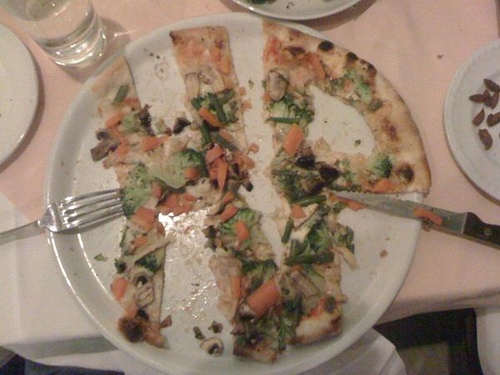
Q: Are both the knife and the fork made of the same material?
A: Yes, both the knife and the fork are made of metal.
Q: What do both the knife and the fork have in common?
A: The material, both the knife and the fork are metallic.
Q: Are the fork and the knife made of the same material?
A: Yes, both the fork and the knife are made of metal.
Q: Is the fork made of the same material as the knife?
A: Yes, both the fork and the knife are made of metal.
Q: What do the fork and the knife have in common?
A: The material, both the fork and the knife are metallic.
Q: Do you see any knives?
A: Yes, there is a knife.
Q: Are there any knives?
A: Yes, there is a knife.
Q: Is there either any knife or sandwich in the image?
A: Yes, there is a knife.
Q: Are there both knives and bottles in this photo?
A: No, there is a knife but no bottles.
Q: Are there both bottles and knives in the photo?
A: No, there is a knife but no bottles.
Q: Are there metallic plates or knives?
A: Yes, there is a metal knife.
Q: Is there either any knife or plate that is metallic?
A: Yes, the knife is metallic.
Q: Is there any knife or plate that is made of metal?
A: Yes, the knife is made of metal.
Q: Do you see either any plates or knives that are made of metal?
A: Yes, the knife is made of metal.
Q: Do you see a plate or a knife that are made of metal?
A: Yes, the knife is made of metal.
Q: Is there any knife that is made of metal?
A: Yes, there is a knife that is made of metal.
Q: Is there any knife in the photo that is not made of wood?
A: Yes, there is a knife that is made of metal.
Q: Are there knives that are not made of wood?
A: Yes, there is a knife that is made of metal.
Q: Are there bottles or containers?
A: No, there are no containers or bottles.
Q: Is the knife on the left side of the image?
A: No, the knife is on the right of the image.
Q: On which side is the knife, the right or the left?
A: The knife is on the right of the image.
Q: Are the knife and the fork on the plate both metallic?
A: Yes, both the knife and the fork are metallic.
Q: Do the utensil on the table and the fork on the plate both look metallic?
A: Yes, both the knife and the fork are metallic.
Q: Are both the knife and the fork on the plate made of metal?
A: Yes, both the knife and the fork are made of metal.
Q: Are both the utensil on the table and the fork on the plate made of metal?
A: Yes, both the knife and the fork are made of metal.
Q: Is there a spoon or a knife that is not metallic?
A: No, there is a knife but it is metallic.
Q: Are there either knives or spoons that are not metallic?
A: No, there is a knife but it is metallic.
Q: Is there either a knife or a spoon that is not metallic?
A: No, there is a knife but it is metallic.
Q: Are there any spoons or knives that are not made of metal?
A: No, there is a knife but it is made of metal.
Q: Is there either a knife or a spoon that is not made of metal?
A: No, there is a knife but it is made of metal.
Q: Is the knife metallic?
A: Yes, the knife is metallic.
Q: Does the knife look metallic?
A: Yes, the knife is metallic.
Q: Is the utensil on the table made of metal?
A: Yes, the knife is made of metal.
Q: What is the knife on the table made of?
A: The knife is made of metal.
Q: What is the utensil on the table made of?
A: The knife is made of metal.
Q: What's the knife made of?
A: The knife is made of metal.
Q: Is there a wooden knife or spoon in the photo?
A: No, there is a knife but it is metallic.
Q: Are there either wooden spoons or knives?
A: No, there is a knife but it is metallic.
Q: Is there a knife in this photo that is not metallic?
A: No, there is a knife but it is metallic.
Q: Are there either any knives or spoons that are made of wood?
A: No, there is a knife but it is made of metal.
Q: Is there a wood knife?
A: No, there is a knife but it is made of metal.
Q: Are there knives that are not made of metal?
A: No, there is a knife but it is made of metal.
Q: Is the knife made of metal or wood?
A: The knife is made of metal.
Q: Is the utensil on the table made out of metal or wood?
A: The knife is made of metal.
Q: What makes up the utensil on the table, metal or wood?
A: The knife is made of metal.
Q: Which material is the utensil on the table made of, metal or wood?
A: The knife is made of metal.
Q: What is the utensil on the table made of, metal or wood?
A: The knife is made of metal.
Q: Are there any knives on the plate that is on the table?
A: Yes, there is a knife on the plate.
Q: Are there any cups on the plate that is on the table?
A: No, there is a knife on the plate.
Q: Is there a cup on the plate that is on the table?
A: No, there is a knife on the plate.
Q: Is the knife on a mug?
A: No, the knife is on the plate.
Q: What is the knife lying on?
A: The knife is lying on the plate.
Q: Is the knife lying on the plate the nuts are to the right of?
A: Yes, the knife is lying on the plate.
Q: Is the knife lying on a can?
A: No, the knife is lying on the plate.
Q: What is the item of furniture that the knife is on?
A: The piece of furniture is a table.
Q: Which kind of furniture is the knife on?
A: The knife is on the table.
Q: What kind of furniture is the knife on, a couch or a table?
A: The knife is on a table.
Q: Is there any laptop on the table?
A: No, there is a knife on the table.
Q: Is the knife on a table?
A: Yes, the knife is on a table.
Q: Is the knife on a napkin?
A: No, the knife is on a table.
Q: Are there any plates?
A: Yes, there is a plate.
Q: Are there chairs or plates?
A: Yes, there is a plate.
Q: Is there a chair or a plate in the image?
A: Yes, there is a plate.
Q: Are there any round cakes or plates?
A: Yes, there is a round plate.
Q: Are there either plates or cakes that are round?
A: Yes, the plate is round.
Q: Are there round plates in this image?
A: Yes, there is a round plate.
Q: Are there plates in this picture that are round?
A: Yes, there is a plate that is round.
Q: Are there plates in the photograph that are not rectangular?
A: Yes, there is a round plate.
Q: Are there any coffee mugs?
A: No, there are no coffee mugs.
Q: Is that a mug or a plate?
A: That is a plate.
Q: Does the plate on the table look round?
A: Yes, the plate is round.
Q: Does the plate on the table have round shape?
A: Yes, the plate is round.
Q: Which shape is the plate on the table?
A: The plate is round.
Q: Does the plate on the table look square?
A: No, the plate is round.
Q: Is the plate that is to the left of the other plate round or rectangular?
A: The plate is round.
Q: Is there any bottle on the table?
A: No, there is a plate on the table.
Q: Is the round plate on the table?
A: Yes, the plate is on the table.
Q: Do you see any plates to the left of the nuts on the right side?
A: Yes, there is a plate to the left of the nuts.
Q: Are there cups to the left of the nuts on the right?
A: No, there is a plate to the left of the nuts.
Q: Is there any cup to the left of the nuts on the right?
A: No, there is a plate to the left of the nuts.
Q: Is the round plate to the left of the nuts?
A: Yes, the plate is to the left of the nuts.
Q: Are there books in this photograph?
A: No, there are no books.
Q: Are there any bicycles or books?
A: No, there are no books or bicycles.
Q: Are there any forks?
A: Yes, there is a fork.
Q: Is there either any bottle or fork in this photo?
A: Yes, there is a fork.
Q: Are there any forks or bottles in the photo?
A: Yes, there is a fork.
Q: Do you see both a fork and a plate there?
A: Yes, there are both a fork and a plate.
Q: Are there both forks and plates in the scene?
A: Yes, there are both a fork and a plate.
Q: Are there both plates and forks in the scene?
A: Yes, there are both a fork and a plate.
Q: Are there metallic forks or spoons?
A: Yes, there is a metal fork.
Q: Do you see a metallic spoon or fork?
A: Yes, there is a metal fork.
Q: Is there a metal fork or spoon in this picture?
A: Yes, there is a metal fork.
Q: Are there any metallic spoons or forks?
A: Yes, there is a metal fork.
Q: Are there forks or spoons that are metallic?
A: Yes, the fork is metallic.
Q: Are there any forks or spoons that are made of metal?
A: Yes, the fork is made of metal.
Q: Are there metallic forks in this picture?
A: Yes, there is a metal fork.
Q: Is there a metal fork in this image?
A: Yes, there is a metal fork.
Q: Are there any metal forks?
A: Yes, there is a metal fork.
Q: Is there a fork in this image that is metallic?
A: Yes, there is a fork that is metallic.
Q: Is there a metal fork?
A: Yes, there is a fork that is made of metal.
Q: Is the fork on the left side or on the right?
A: The fork is on the left of the image.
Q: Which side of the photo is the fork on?
A: The fork is on the left of the image.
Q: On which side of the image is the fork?
A: The fork is on the left of the image.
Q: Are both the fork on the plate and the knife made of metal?
A: Yes, both the fork and the knife are made of metal.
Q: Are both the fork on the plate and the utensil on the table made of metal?
A: Yes, both the fork and the knife are made of metal.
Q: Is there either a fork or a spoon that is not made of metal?
A: No, there is a fork but it is made of metal.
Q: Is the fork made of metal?
A: Yes, the fork is made of metal.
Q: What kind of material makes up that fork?
A: The fork is made of metal.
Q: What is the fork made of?
A: The fork is made of metal.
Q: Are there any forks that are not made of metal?
A: No, there is a fork but it is made of metal.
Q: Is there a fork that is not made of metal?
A: No, there is a fork but it is made of metal.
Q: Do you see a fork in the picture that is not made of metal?
A: No, there is a fork but it is made of metal.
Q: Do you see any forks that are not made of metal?
A: No, there is a fork but it is made of metal.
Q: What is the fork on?
A: The fork is on the plate.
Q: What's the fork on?
A: The fork is on the plate.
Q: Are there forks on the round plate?
A: Yes, there is a fork on the plate.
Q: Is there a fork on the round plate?
A: Yes, there is a fork on the plate.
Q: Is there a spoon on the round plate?
A: No, there is a fork on the plate.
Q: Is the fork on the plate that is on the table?
A: Yes, the fork is on the plate.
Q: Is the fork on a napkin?
A: No, the fork is on the plate.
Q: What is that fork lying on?
A: The fork is lying on the plate.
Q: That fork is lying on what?
A: The fork is lying on the plate.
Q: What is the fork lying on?
A: The fork is lying on the plate.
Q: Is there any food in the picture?
A: Yes, there is food.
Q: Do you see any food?
A: Yes, there is food.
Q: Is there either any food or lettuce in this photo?
A: Yes, there is food.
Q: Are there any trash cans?
A: No, there are no trash cans.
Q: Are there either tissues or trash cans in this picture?
A: No, there are no trash cans or tissues.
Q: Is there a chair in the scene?
A: No, there are no chairs.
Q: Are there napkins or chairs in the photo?
A: No, there are no chairs or napkins.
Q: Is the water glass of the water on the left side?
A: Yes, the water glass is on the left of the image.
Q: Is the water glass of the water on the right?
A: No, the water glass is on the left of the image.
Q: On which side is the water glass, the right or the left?
A: The water glass is on the left of the image.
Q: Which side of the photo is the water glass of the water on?
A: The water glass is on the left of the image.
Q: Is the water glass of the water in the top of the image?
A: Yes, the water glass is in the top of the image.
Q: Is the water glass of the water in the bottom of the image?
A: No, the water glass is in the top of the image.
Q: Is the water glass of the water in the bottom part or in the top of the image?
A: The water glass is in the top of the image.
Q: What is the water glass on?
A: The water glass is on the table.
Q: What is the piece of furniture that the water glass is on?
A: The piece of furniture is a table.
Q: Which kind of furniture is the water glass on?
A: The water glass is on the table.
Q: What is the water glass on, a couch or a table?
A: The water glass is on a table.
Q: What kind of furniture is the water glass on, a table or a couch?
A: The water glass is on a table.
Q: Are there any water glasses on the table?
A: Yes, there is a water glass on the table.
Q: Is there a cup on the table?
A: No, there is a water glass on the table.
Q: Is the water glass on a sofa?
A: No, the water glass is on the table.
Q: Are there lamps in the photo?
A: No, there are no lamps.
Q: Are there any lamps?
A: No, there are no lamps.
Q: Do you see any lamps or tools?
A: No, there are no lamps or tools.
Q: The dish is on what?
A: The dish is on the plate.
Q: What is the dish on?
A: The dish is on the plate.